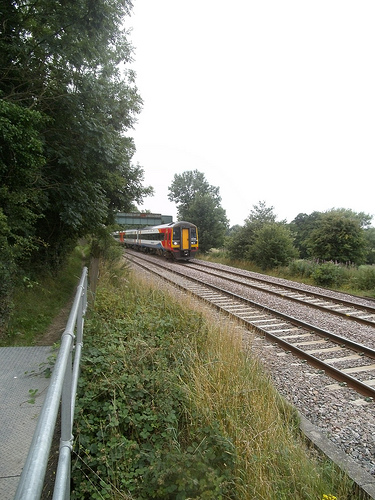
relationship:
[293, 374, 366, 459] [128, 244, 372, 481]
pebbles by tracks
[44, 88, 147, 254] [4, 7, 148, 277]
leaves on tree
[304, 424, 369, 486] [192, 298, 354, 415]
barrier near tracks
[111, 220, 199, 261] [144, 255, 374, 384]
passenger train on track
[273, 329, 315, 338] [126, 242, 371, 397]
railroad tie on track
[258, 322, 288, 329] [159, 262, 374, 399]
railroad tie on track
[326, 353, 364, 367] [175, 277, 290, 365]
railroad tie on track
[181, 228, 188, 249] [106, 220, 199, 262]
door on train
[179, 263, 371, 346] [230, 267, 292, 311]
gravel under tracks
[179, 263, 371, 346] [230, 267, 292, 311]
gravel next to tracks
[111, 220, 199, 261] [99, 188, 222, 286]
passenger train of train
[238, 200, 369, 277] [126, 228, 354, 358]
trees by tracks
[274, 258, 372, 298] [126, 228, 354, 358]
bushes by tracks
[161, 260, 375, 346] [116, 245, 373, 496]
gravel on tracks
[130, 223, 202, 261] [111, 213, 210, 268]
front car on passenger train